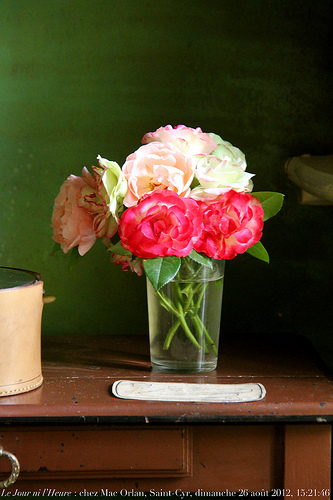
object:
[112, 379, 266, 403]
dish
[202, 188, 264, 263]
flower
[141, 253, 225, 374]
cup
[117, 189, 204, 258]
flower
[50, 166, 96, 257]
flower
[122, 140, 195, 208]
flower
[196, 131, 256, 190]
flower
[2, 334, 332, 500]
desk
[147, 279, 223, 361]
water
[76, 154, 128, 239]
flower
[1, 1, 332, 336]
wall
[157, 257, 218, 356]
stems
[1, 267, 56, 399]
container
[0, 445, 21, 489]
handle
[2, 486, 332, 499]
copywrite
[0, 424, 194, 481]
drawer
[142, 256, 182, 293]
leaf